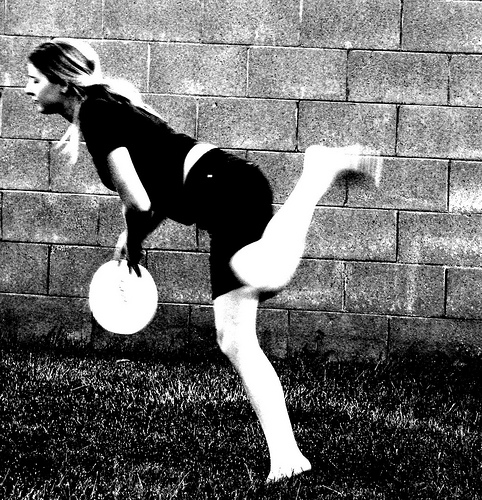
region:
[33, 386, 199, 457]
grass on the ground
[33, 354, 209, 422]
white line on the grass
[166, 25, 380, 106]
white chalk on the wall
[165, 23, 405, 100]
square tiles in the wall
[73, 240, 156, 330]
white Frisbee in girl's hand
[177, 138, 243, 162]
woman's bare skin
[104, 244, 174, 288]
woman's fingers on frisbee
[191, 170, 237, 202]
small spot on black shorts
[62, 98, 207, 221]
black short sleeve shirt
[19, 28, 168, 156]
woman's long blonde hair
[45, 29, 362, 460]
this is a woman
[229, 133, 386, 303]
the womans left leg is bent above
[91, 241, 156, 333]
the woman is holding a plate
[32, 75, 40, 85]
the womans eye is closed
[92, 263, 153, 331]
the plate is white in color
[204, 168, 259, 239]
the woman has black shorts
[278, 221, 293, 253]
the woman is light skinned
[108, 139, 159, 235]
the womans left hand is bent in front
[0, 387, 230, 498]
the grass are short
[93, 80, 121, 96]
the woman has long hair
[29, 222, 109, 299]
Frisbee in person's hand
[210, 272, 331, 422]
Person standing on one leg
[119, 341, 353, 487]
Person standing in grass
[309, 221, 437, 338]
Brick wall behind woman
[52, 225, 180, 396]
Frisbee in hand is white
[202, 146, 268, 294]
Person wearing black shorts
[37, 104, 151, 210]
Person wearing black shirt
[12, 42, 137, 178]
Person has long hair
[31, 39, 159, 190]
Person's hair in pony tail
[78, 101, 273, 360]
Person wearing dark clothing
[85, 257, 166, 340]
Woman holding a frisbee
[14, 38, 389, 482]
Woman in a running position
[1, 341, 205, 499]
Grass on the ground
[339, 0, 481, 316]
Part of a brick wall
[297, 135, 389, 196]
Woman's foot in the air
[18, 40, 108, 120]
Woman with eyes closed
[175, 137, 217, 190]
Part of woman's back showing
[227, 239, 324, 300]
The woman's knee bent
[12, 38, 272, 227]
Woman leaning forward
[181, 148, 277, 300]
Woman wearing shorts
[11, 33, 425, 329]
a woman holding a frisbee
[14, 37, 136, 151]
a woman with long hair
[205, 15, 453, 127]
a cement block wall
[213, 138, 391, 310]
a woman's leg bent upward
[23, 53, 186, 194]
a woman wearing a black shirt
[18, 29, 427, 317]
a woman wearing black shirt and shorts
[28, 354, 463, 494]
a patch of grass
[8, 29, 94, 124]
the side of a woman's face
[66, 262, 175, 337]
a white frisbee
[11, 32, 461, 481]
a woman bent over with leg up off the ground